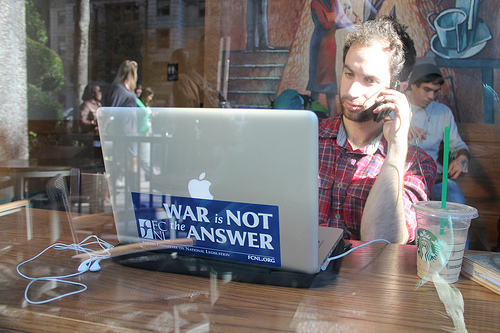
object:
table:
[0, 205, 499, 333]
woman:
[79, 80, 102, 135]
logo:
[415, 227, 441, 262]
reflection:
[0, 108, 219, 333]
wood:
[90, 281, 412, 333]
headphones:
[15, 236, 115, 305]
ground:
[0, 0, 500, 184]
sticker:
[130, 190, 282, 268]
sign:
[167, 63, 178, 80]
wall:
[0, 0, 500, 254]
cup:
[407, 124, 480, 284]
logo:
[187, 172, 214, 207]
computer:
[93, 107, 347, 290]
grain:
[228, 301, 288, 312]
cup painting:
[429, 9, 491, 59]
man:
[314, 18, 436, 245]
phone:
[372, 82, 399, 124]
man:
[404, 62, 470, 251]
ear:
[402, 81, 409, 89]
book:
[460, 251, 499, 295]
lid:
[409, 201, 479, 221]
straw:
[438, 125, 449, 235]